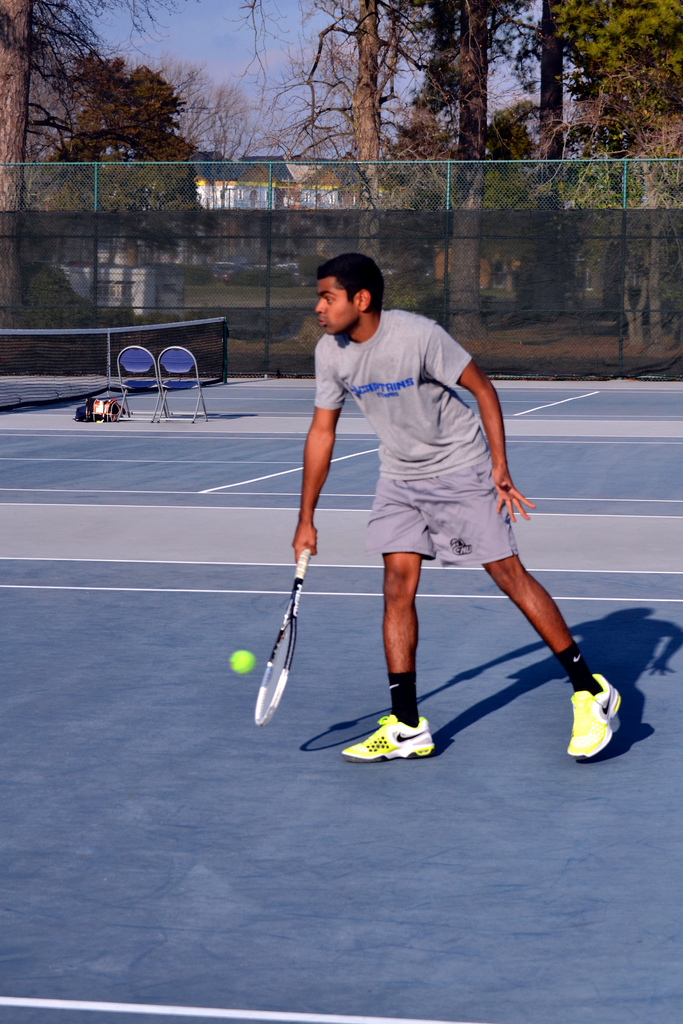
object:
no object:
[301, 597, 682, 766]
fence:
[2, 161, 681, 396]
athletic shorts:
[364, 465, 524, 564]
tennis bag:
[75, 399, 126, 426]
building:
[193, 150, 362, 287]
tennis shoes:
[340, 673, 622, 763]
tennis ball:
[230, 646, 256, 673]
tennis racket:
[253, 540, 313, 727]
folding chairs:
[115, 345, 218, 428]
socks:
[382, 636, 602, 724]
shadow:
[295, 591, 677, 756]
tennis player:
[291, 254, 623, 771]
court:
[1, 369, 677, 1020]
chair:
[117, 343, 207, 423]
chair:
[156, 345, 218, 425]